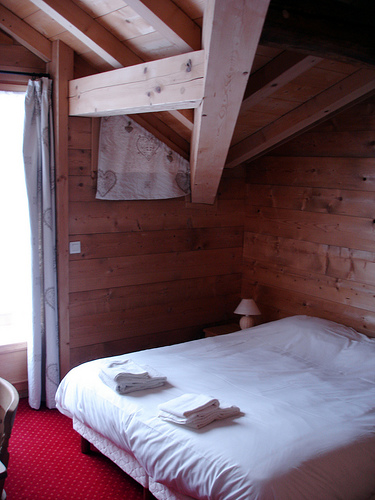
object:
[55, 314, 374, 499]
bed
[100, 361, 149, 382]
towels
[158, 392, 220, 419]
towels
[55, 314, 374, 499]
sheet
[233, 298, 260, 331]
lamp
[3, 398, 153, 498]
carpet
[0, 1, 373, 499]
room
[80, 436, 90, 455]
post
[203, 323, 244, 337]
nightstand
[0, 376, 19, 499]
chair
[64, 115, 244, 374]
wall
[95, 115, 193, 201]
curtain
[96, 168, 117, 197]
heart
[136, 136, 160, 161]
heart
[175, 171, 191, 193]
heart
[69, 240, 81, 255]
light switch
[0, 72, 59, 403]
door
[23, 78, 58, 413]
curtain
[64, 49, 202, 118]
rafter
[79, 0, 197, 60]
rafter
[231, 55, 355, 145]
rafter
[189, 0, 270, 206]
rafter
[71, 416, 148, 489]
box spring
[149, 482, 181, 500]
box spring